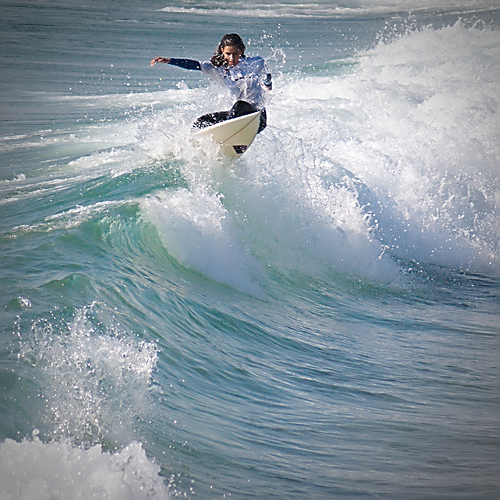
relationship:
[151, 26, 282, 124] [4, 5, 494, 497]
person riding in water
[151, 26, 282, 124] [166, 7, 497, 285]
person riding wave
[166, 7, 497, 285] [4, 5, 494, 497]
wave across water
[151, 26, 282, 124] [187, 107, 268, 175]
person riding on surfboard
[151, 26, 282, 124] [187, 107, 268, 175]
person standing on surfboard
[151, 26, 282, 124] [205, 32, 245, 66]
person has hair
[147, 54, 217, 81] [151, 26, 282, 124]
arm of person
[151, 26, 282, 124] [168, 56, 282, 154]
person wearing wetsuit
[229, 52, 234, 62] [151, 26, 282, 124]
nose of person